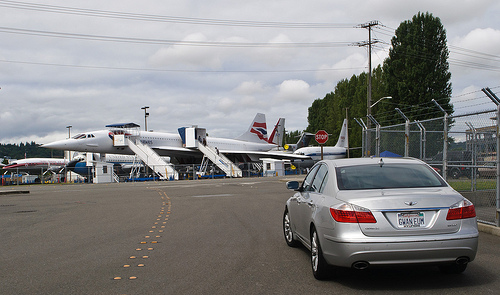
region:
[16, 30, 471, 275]
There a planes in the background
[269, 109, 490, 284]
There is a silver car in the foreground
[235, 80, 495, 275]
There is fence that is near the silver car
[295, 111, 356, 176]
There is a stop sign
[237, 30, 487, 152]
There are trees in the background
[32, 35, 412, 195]
There are clouds in the sky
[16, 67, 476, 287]
There are people in the photo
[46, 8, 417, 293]
The photo was taken during the daytime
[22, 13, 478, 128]
There are powerlines near the trees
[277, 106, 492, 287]
The silver car has its lights off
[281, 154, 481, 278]
silver car approaching stop sign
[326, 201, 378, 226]
left rear light assembly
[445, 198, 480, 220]
right rear light assembly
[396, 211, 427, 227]
license plate of silver car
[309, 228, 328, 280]
left rear tire of car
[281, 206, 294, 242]
left front tire of car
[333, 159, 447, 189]
rear window of car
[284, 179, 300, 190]
left side mirror of car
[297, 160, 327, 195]
windows on side of car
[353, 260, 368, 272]
exhaust tail pipe on left of car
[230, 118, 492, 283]
Silver car on the street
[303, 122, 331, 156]
Red and white stop sign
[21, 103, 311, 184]
Large white airplane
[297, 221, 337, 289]
Black rubber car tire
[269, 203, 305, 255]
Black rubber car tire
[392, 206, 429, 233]
White license plate with black lettering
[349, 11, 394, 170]
Wooden power pole with transformers on top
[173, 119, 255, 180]
White airplane loading ramp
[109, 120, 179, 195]
White airplane loading ramp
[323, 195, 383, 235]
Plastic car tail light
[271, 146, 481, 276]
silver car on the road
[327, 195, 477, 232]
two lights on the back of the car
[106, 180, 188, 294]
yellow dots on the road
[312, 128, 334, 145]
red sign with white letters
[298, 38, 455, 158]
trees standing in the background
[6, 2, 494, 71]
power lines hanging in the sky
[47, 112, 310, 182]
stationary airplane in the lot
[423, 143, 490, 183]
black SUV parked behind the fence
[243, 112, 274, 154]
back wing of the airplane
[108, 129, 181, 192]
stairs leading to the airplane entrance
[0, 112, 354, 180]
Airplanes at the airport.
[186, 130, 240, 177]
People walking down the stairs on the plane.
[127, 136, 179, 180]
White stairs from the plane.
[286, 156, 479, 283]
Silver car moving towards the airport.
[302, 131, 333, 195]
Stop sign at the airport.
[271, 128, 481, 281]
Driver preparing to stop at the stop sign.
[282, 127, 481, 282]
Silver car near the stop sign.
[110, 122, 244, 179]
Two sets of stairs on plane.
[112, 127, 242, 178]
Two sets of stairs on the plane's doorways.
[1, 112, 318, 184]
Aircraft secured with metal fence.